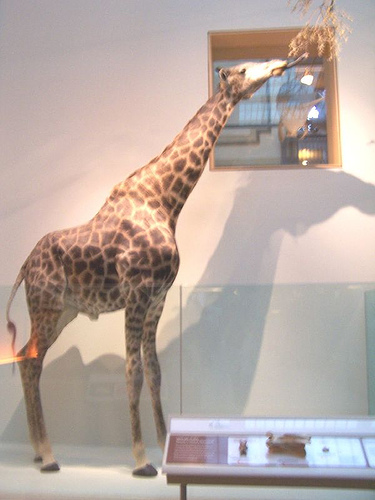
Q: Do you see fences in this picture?
A: No, there are no fences.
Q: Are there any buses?
A: No, there are no buses.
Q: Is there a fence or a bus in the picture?
A: No, there are no buses or fences.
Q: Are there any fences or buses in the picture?
A: No, there are no buses or fences.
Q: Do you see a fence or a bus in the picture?
A: No, there are no buses or fences.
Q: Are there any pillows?
A: No, there are no pillows.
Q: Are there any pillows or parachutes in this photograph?
A: No, there are no pillows or parachutes.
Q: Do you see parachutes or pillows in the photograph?
A: No, there are no pillows or parachutes.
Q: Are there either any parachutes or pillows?
A: No, there are no pillows or parachutes.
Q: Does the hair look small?
A: Yes, the hair is small.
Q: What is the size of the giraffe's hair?
A: The hair is small.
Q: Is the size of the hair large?
A: No, the hair is small.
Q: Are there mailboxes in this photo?
A: No, there are no mailboxes.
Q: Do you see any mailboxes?
A: No, there are no mailboxes.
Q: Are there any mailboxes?
A: No, there are no mailboxes.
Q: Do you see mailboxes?
A: No, there are no mailboxes.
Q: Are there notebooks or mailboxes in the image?
A: No, there are no mailboxes or notebooks.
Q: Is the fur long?
A: Yes, the fur is long.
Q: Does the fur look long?
A: Yes, the fur is long.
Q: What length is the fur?
A: The fur is long.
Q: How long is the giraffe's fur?
A: The fur is long.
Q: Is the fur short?
A: No, the fur is long.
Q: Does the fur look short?
A: No, the fur is long.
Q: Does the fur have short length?
A: No, the fur is long.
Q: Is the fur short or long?
A: The fur is long.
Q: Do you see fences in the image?
A: No, there are no fences.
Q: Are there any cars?
A: No, there are no cars.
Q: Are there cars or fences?
A: No, there are no cars or fences.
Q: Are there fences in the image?
A: No, there are no fences.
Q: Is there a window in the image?
A: Yes, there is a window.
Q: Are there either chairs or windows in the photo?
A: Yes, there is a window.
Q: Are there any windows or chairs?
A: Yes, there is a window.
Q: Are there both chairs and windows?
A: No, there is a window but no chairs.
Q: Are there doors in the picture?
A: No, there are no doors.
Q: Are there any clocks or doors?
A: No, there are no doors or clocks.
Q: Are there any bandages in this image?
A: No, there are no bandages.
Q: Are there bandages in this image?
A: No, there are no bandages.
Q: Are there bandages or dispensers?
A: No, there are no bandages or dispensers.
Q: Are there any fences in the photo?
A: No, there are no fences.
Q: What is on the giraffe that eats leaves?
A: The spots are on the giraffe.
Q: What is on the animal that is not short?
A: The spots are on the giraffe.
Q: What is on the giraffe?
A: The spots are on the giraffe.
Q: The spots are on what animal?
A: The spots are on the giraffe.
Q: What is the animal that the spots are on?
A: The animal is a giraffe.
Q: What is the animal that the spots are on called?
A: The animal is a giraffe.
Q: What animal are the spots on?
A: The spots are on the giraffe.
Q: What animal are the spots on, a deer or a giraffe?
A: The spots are on a giraffe.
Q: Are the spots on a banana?
A: No, the spots are on the giraffe.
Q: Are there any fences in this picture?
A: No, there are no fences.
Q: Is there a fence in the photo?
A: No, there are no fences.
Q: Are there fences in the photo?
A: No, there are no fences.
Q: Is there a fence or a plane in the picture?
A: No, there are no fences or airplanes.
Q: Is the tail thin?
A: Yes, the tail is thin.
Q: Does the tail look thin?
A: Yes, the tail is thin.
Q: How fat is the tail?
A: The tail is thin.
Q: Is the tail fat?
A: No, the tail is thin.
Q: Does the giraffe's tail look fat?
A: No, the tail is thin.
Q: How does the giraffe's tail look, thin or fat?
A: The tail is thin.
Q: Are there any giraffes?
A: Yes, there is a giraffe.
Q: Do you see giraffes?
A: Yes, there is a giraffe.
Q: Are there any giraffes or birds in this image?
A: Yes, there is a giraffe.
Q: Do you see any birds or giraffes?
A: Yes, there is a giraffe.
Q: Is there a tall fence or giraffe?
A: Yes, there is a tall giraffe.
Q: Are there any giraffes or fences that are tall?
A: Yes, the giraffe is tall.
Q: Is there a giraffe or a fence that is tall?
A: Yes, the giraffe is tall.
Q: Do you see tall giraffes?
A: Yes, there is a tall giraffe.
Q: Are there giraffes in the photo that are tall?
A: Yes, there is a giraffe that is tall.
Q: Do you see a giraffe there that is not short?
A: Yes, there is a tall giraffe.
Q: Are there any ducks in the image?
A: No, there are no ducks.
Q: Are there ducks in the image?
A: No, there are no ducks.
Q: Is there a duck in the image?
A: No, there are no ducks.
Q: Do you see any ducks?
A: No, there are no ducks.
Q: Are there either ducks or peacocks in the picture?
A: No, there are no ducks or peacocks.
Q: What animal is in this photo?
A: The animal is a giraffe.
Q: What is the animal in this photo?
A: The animal is a giraffe.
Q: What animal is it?
A: The animal is a giraffe.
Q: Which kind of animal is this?
A: This is a giraffe.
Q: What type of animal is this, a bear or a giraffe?
A: This is a giraffe.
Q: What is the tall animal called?
A: The animal is a giraffe.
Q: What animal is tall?
A: The animal is a giraffe.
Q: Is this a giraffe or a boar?
A: This is a giraffe.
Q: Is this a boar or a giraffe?
A: This is a giraffe.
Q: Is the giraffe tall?
A: Yes, the giraffe is tall.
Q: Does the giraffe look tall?
A: Yes, the giraffe is tall.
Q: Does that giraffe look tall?
A: Yes, the giraffe is tall.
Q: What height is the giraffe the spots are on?
A: The giraffe is tall.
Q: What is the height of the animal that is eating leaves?
A: The giraffe is tall.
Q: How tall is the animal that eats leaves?
A: The giraffe is tall.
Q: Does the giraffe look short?
A: No, the giraffe is tall.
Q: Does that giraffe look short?
A: No, the giraffe is tall.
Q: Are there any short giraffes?
A: No, there is a giraffe but it is tall.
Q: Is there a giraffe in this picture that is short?
A: No, there is a giraffe but it is tall.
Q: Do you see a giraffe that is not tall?
A: No, there is a giraffe but it is tall.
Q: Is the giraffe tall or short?
A: The giraffe is tall.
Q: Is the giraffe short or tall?
A: The giraffe is tall.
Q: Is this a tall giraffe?
A: Yes, this is a tall giraffe.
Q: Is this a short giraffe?
A: No, this is a tall giraffe.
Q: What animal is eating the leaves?
A: The giraffe is eating the leaves.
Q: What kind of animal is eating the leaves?
A: The animal is a giraffe.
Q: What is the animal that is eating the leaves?
A: The animal is a giraffe.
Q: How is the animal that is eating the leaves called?
A: The animal is a giraffe.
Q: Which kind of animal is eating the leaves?
A: The animal is a giraffe.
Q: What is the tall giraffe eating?
A: The giraffe is eating leaves.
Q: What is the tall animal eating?
A: The giraffe is eating leaves.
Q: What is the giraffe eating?
A: The giraffe is eating leaves.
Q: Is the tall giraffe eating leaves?
A: Yes, the giraffe is eating leaves.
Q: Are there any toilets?
A: No, there are no toilets.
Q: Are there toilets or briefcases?
A: No, there are no toilets or briefcases.